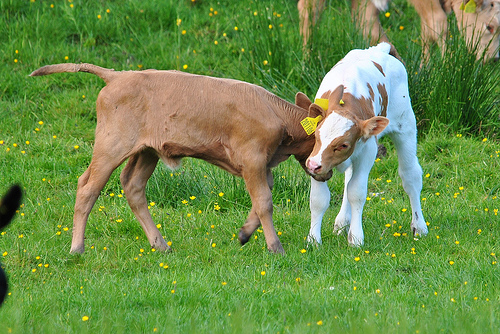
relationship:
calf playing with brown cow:
[304, 40, 431, 250] [27, 62, 328, 255]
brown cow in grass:
[27, 62, 328, 255] [1, 0, 499, 330]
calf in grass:
[304, 40, 431, 250] [2, 0, 371, 333]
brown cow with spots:
[27, 62, 328, 255] [364, 61, 391, 124]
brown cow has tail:
[27, 62, 328, 255] [30, 51, 110, 97]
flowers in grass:
[156, 1, 405, 76] [1, 0, 499, 330]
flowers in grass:
[425, 132, 497, 332] [1, 0, 499, 330]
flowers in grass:
[164, 177, 232, 332] [1, 0, 499, 330]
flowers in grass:
[376, 211, 411, 270] [1, 0, 499, 330]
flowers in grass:
[3, 115, 54, 158] [1, 0, 499, 330]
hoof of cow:
[231, 222, 251, 249] [25, 48, 360, 259]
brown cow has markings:
[27, 62, 328, 255] [309, 58, 387, 128]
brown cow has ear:
[27, 62, 328, 255] [300, 100, 324, 130]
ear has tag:
[300, 100, 324, 130] [294, 110, 319, 137]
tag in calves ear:
[301, 112, 314, 132] [295, 89, 337, 130]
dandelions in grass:
[354, 254, 362, 262] [1, 0, 499, 330]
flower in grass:
[362, 249, 368, 255] [1, 0, 499, 330]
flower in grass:
[453, 239, 461, 246] [1, 0, 499, 330]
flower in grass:
[449, 295, 457, 303] [1, 0, 499, 330]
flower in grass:
[454, 185, 466, 190] [1, 0, 499, 330]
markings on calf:
[373, 90, 393, 122] [305, 40, 431, 250]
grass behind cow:
[173, 23, 274, 75] [295, 43, 482, 240]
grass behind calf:
[173, 23, 274, 75] [39, 21, 338, 288]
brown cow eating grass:
[27, 62, 328, 255] [205, 278, 412, 326]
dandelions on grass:
[353, 250, 363, 265] [1, 0, 499, 330]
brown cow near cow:
[27, 62, 328, 255] [304, 35, 434, 261]